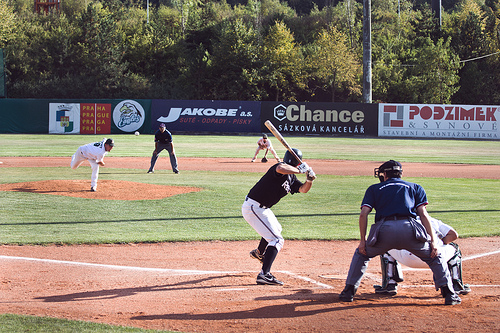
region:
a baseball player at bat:
[240, 120, 315, 285]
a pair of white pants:
[240, 197, 285, 251]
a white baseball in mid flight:
[133, 130, 138, 134]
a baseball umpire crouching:
[335, 158, 457, 303]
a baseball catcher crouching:
[371, 212, 467, 293]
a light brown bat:
[262, 118, 302, 164]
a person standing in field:
[145, 122, 180, 174]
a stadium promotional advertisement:
[260, 100, 375, 135]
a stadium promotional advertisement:
[149, 100, 259, 135]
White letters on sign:
[155, 105, 255, 125]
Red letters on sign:
[178, 115, 254, 126]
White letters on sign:
[276, 122, 365, 136]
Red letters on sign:
[406, 104, 498, 122]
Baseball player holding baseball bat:
[238, 119, 317, 288]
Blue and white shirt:
[359, 178, 429, 218]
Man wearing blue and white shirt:
[336, 159, 462, 307]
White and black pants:
[239, 196, 285, 251]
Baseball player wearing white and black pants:
[238, 145, 317, 287]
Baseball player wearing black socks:
[239, 147, 315, 285]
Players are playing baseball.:
[26, 116, 459, 309]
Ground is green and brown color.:
[28, 176, 165, 296]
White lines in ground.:
[26, 239, 362, 304]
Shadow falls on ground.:
[11, 199, 431, 325]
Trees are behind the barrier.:
[11, 32, 499, 82]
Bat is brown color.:
[248, 112, 331, 188]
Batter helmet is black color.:
[280, 140, 313, 181]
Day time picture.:
[16, 15, 480, 316]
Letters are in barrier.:
[35, 99, 497, 151]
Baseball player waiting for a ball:
[238, 117, 317, 289]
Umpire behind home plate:
[337, 157, 462, 309]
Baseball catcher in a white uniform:
[375, 214, 471, 296]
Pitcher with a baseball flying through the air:
[69, 129, 140, 193]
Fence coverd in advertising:
[0, 95, 499, 140]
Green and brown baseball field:
[1, 129, 498, 331]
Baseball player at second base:
[248, 132, 282, 164]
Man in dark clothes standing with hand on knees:
[147, 120, 180, 175]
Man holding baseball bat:
[239, 117, 316, 288]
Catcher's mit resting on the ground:
[259, 155, 268, 162]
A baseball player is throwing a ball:
[68, 131, 147, 195]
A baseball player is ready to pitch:
[240, 117, 319, 287]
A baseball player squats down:
[343, 158, 463, 308]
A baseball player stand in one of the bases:
[244, 130, 283, 165]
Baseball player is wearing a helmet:
[281, 145, 307, 170]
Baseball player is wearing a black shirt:
[248, 162, 313, 207]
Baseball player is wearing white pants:
[238, 196, 288, 250]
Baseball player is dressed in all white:
[72, 133, 112, 190]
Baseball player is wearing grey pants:
[348, 215, 458, 288]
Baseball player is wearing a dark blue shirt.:
[359, 178, 436, 220]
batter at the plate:
[220, 118, 345, 275]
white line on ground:
[98, 253, 194, 291]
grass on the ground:
[130, 203, 201, 239]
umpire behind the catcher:
[333, 153, 433, 253]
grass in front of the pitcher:
[95, 204, 222, 238]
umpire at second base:
[123, 103, 195, 198]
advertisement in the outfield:
[271, 88, 396, 140]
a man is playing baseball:
[243, 120, 313, 282]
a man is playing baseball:
[377, 212, 466, 294]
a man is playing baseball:
[73, 139, 113, 192]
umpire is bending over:
[152, 121, 177, 176]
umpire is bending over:
[342, 159, 459, 304]